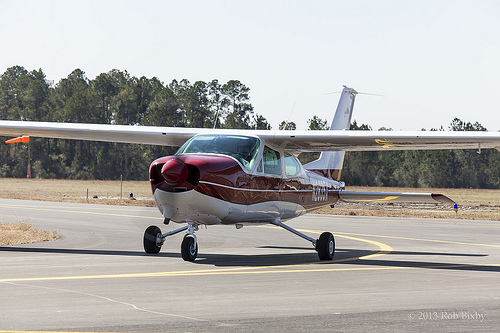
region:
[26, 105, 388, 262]
red and white airplane on street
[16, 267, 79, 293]
gray street pavement with yellow stripe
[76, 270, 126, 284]
gray street pavement with yellow stripe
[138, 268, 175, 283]
gray street pavement with yellow stripe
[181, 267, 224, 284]
gray street pavement with yellow stripe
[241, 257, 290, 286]
gray street pavement with yellow stripe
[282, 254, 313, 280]
gray street pavement with yellow stripe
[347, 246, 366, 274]
gray street pavement with yellow stripe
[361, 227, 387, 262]
gray street pavement with yellow stripe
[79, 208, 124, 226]
gray street pavement with yellow stripe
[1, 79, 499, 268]
THIS IS A PLANE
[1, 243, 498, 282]
THIS IS A SHADOW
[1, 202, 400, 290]
THIS IS A YELLOW STRIPE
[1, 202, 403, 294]
THE STRIPE IS PAINTED ON THE ROAD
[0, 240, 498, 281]
THE SHADOW IS ON THE ROAD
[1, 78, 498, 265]
THE PLANE IS WHITE AND RED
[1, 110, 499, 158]
THE PLANE HAS WINGS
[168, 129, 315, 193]
THE PLANE HAS WINDOWS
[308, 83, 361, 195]
THE PLANE HAS A TAIL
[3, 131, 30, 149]
THE WINDSOCK IS ORANGE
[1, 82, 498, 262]
a plane on a runway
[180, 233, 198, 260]
front wheel of a plane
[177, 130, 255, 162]
cockpit window on a plane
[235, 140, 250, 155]
the head of a piolt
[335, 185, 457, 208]
rear wing of a plane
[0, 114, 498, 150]
wing of a plane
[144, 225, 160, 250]
right wheel on a plane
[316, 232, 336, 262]
left wheel on a plane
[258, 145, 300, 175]
side windows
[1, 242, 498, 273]
shadow of a plane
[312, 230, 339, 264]
tire of an airplane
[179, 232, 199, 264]
tire of an airplane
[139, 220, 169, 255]
tire of an airplane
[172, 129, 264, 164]
windshield on an airplane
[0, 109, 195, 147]
wing of an airplane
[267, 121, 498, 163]
wing of an airplane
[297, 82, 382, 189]
tail of an airplane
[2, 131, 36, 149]
orange flag flying in the wind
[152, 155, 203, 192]
red nose of an airplane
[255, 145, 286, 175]
window on an airplane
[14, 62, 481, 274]
small white and red plane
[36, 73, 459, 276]
small plane on a runway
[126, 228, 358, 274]
three black small wheels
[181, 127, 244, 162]
front window of plane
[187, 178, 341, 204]
red and white stripe on side of plane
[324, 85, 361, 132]
tail fin of plane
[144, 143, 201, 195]
propeller on front of plane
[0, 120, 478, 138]
wingspan of small plane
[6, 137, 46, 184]
orange wind cone on pole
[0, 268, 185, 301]
yellow lines on runway